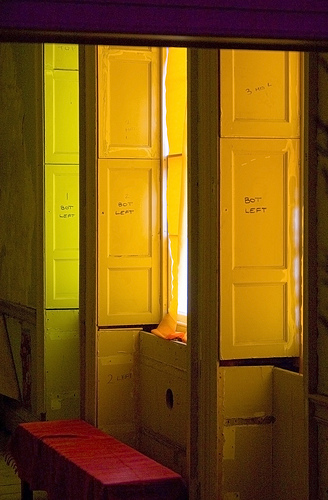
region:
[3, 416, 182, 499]
red fabric covered bench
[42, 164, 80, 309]
white painted wood cabinet panel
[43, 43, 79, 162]
white painted wood cabinet panel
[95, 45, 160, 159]
white painted wood cabinet panel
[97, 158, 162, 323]
white painted wood cabinet panel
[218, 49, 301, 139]
white painted wood cabinet panel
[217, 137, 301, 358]
white painted wood cabinet panel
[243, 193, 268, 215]
the words bot left written in black marker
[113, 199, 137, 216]
the words bot left written in black marker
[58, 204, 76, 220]
the words bot left written in black marker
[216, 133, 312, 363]
wooden panel is marked bot left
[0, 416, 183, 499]
red fringed blanket on a table top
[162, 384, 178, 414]
a circular hole in a piece of wood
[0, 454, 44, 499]
wooden floor boards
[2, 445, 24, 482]
fringe on the edge of a red blanket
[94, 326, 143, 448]
board marked 2 left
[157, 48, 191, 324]
light coming in through a window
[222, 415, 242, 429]
holes in a piece of board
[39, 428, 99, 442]
a crease in the top of a blanket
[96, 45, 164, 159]
paneled piece of wood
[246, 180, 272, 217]
The door says bot left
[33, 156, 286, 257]
The doors say bot left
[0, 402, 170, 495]
The table is red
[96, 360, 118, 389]
2 is written on the wall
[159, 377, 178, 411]
A hole is on the wall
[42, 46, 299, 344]
the doors are different colors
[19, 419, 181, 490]
table in front of the doors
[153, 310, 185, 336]
yellow fabric on the windowsill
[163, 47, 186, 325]
drapes on the window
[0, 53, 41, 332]
the wall needs to be repainted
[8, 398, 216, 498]
A red bench sits in front of a window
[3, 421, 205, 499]
A red cloth covers the bench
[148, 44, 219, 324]
A window lights up the walls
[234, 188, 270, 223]
Writting on a piece of wall that says "Bot Left"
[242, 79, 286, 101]
Writing that says "3 mrs L"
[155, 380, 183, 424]
A round hole in the wall near the bench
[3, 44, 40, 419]
Part of the wall in the room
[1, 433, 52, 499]
The wooden floor on which the bench stands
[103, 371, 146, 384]
Writing on the wall that says "2 lift"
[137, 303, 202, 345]
A red piece of material in front of the window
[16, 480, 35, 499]
leg of wooden bench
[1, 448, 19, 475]
loose strings at the end of red cloth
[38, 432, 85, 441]
wrinkle in red cloth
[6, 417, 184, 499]
red cloth draped over bench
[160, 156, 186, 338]
window with curtain closed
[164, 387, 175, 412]
hole in wall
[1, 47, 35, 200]
paint pilled from wall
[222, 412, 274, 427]
torn sheet rock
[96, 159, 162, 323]
white shutter for window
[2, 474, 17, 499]
ground made of wooden planks